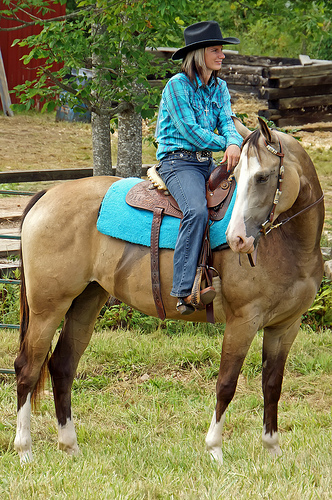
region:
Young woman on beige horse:
[153, 18, 243, 312]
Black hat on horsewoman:
[167, 18, 238, 58]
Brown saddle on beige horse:
[124, 160, 233, 219]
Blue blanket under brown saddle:
[96, 175, 234, 248]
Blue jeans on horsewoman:
[155, 149, 210, 298]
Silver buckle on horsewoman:
[191, 146, 210, 163]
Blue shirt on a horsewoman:
[153, 69, 243, 155]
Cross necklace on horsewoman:
[201, 101, 209, 113]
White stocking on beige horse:
[203, 407, 226, 467]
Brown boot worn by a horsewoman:
[172, 284, 215, 313]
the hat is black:
[165, 21, 237, 56]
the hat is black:
[168, 19, 250, 79]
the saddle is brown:
[130, 171, 232, 241]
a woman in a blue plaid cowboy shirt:
[155, 20, 241, 312]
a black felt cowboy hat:
[171, 21, 240, 59]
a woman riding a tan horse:
[13, 20, 324, 470]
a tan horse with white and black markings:
[12, 115, 325, 468]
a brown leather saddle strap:
[149, 207, 166, 321]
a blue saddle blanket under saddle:
[95, 177, 235, 250]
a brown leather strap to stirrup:
[189, 223, 209, 307]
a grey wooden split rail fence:
[144, 47, 331, 130]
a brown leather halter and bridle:
[259, 142, 323, 234]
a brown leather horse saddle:
[127, 164, 236, 221]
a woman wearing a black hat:
[160, 16, 246, 95]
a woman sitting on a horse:
[113, 27, 298, 239]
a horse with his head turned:
[169, 97, 312, 484]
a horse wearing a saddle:
[69, 30, 268, 296]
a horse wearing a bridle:
[189, 126, 326, 279]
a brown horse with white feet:
[8, 83, 303, 496]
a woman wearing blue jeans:
[142, 27, 233, 238]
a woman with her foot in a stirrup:
[154, 24, 237, 359]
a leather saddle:
[112, 126, 259, 230]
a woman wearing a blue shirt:
[156, 24, 239, 172]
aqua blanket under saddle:
[125, 199, 151, 245]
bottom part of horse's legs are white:
[19, 408, 73, 459]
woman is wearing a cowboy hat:
[176, 23, 240, 46]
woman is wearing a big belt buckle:
[195, 148, 214, 165]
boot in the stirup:
[170, 286, 236, 320]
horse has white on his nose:
[232, 174, 243, 244]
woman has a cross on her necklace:
[204, 107, 214, 118]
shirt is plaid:
[164, 85, 194, 119]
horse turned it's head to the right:
[227, 173, 279, 256]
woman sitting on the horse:
[147, 128, 213, 228]